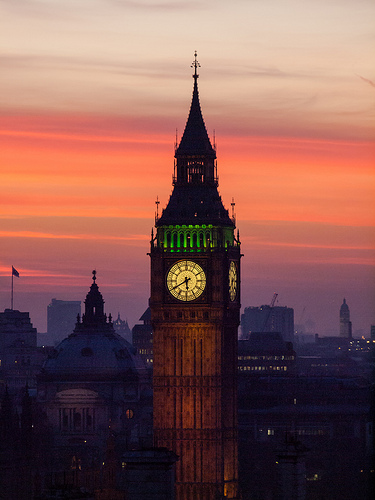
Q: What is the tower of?
A: Big ben.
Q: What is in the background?
A: Tall city building.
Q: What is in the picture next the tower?
A: Building with a dome.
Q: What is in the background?
A: Sky.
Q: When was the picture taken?
A: Sunset.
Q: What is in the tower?
A: Clocks.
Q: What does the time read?
A: 5:40.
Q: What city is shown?
A: London.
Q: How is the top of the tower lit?
A: With green lights.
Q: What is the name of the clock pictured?
A: Big Ben.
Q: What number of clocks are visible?
A: Two.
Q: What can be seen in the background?
A: Cityscape.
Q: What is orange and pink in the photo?
A: Sky.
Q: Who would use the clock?
A: Tourists.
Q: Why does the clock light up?
A: To see it in the dark.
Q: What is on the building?
A: A clock.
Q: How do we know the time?
A: The clock.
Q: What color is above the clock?
A: Green.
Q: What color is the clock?
A: Gold and black.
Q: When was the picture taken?
A: Evening.